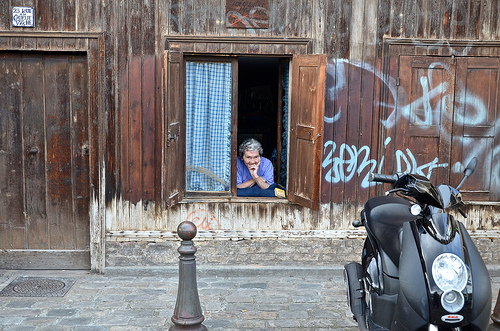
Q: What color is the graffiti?
A: Light blue.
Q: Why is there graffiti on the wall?
A: Gang activity.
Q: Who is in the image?
A: An elderly person looking out the window.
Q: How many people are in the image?
A: One.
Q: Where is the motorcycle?
A: In front of the window.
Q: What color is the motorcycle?
A: Black.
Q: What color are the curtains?
A: Blue and white.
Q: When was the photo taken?
A: Daytime.